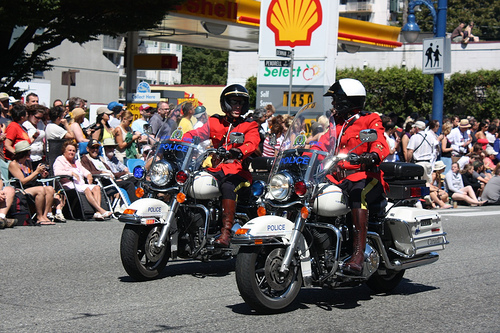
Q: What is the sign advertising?
A: Gas prices.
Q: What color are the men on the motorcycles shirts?
A: Red.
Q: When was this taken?
A: During the daytime.